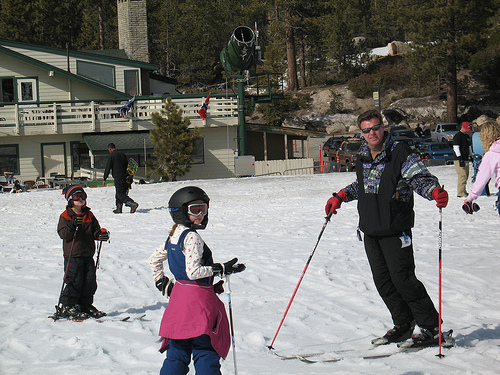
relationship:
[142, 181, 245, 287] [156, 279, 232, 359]
girl wearing jacket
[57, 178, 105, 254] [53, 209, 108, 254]
child wearing jacket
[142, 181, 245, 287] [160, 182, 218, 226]
girl wearing helmet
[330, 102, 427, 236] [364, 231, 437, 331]
man wearing pants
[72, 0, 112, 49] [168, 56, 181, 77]
tree has branches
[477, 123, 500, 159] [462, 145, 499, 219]
woman wearing sweater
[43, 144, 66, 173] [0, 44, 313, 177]
door on side of house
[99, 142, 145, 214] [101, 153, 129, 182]
man wearing shirt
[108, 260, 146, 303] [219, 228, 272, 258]
tracks are on top of snow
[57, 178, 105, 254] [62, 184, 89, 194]
child wearing hat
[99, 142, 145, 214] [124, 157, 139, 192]
man carrying snowboard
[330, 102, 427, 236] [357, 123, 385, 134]
man wearing sunglasses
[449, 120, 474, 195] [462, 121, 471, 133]
man wearing cap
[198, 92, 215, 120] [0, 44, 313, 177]
flag on front of house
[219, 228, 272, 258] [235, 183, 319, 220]
snow on ground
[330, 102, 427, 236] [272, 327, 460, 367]
man on skis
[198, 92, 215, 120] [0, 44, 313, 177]
flag hanging on house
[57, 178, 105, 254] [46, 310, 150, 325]
child wearing skis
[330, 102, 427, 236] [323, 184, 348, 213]
man wearing glove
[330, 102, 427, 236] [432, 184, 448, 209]
man wearing glove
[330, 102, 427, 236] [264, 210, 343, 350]
man holding ski pole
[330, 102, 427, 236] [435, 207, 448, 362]
man holding ski pole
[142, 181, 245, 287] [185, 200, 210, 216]
girl wearing goggles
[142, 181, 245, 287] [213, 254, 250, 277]
girl wearing glove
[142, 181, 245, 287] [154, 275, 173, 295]
girl wearing glove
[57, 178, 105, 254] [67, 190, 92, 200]
child wearing goggles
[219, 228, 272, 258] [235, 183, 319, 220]
snow on top of ground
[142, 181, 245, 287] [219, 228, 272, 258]
girl standing on snow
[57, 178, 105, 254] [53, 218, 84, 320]
child holding ski pole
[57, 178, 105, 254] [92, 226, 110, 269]
child holding ski pole